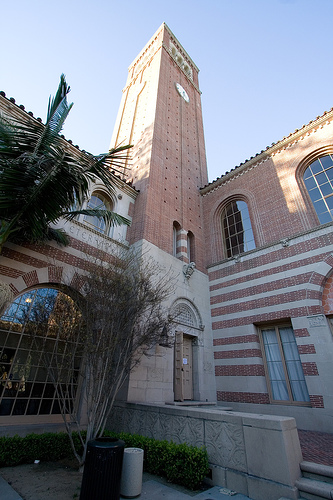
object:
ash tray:
[121, 447, 144, 498]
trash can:
[84, 437, 124, 499]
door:
[173, 332, 183, 400]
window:
[255, 317, 311, 404]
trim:
[257, 319, 314, 407]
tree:
[14, 235, 186, 474]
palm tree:
[1, 74, 130, 254]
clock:
[176, 80, 192, 100]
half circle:
[213, 187, 252, 214]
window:
[219, 197, 259, 260]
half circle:
[292, 148, 332, 173]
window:
[292, 145, 333, 228]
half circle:
[91, 185, 116, 201]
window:
[82, 189, 113, 234]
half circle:
[7, 268, 102, 315]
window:
[2, 285, 87, 417]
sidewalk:
[298, 430, 332, 462]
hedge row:
[1, 430, 207, 488]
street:
[1, 463, 250, 499]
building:
[0, 22, 332, 446]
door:
[183, 333, 195, 401]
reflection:
[1, 291, 85, 391]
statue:
[181, 261, 196, 279]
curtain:
[257, 323, 310, 401]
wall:
[102, 398, 303, 498]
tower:
[107, 22, 210, 274]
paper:
[183, 358, 190, 366]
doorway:
[174, 331, 196, 401]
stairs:
[295, 461, 332, 498]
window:
[173, 222, 177, 257]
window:
[190, 235, 195, 262]